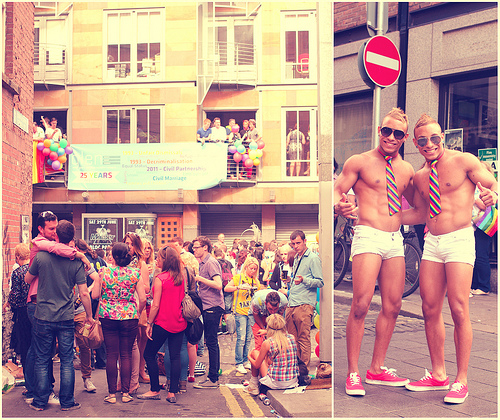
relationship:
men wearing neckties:
[339, 106, 472, 240] [383, 162, 447, 232]